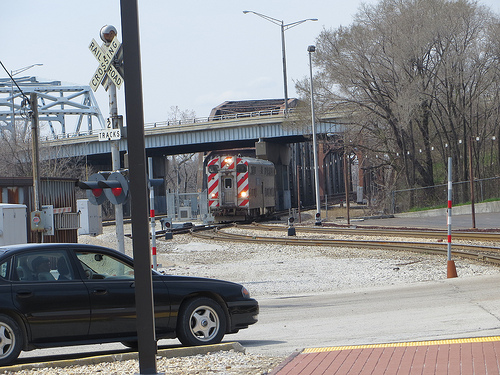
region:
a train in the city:
[18, 21, 486, 333]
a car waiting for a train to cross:
[2, 225, 264, 356]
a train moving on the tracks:
[195, 137, 311, 230]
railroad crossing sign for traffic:
[52, 26, 172, 249]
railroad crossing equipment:
[23, 31, 170, 238]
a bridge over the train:
[28, 93, 390, 227]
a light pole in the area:
[235, 1, 335, 111]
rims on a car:
[181, 293, 233, 348]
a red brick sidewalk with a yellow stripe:
[288, 341, 493, 374]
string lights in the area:
[288, 134, 493, 181]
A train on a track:
[205, 155, 276, 221]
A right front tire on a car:
[177, 297, 226, 344]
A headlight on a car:
[242, 285, 249, 297]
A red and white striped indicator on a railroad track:
[445, 155, 453, 275]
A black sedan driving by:
[0, 243, 257, 368]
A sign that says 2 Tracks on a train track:
[98, 117, 120, 141]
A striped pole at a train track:
[150, 156, 154, 268]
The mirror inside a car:
[93, 253, 103, 260]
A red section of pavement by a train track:
[271, 335, 498, 372]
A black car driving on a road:
[1, 243, 258, 365]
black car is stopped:
[5, 249, 270, 354]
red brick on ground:
[290, 335, 497, 373]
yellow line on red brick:
[304, 323, 495, 365]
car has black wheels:
[172, 290, 232, 337]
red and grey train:
[186, 147, 276, 227]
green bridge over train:
[19, 103, 354, 164]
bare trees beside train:
[304, 20, 495, 183]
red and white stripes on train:
[202, 157, 241, 214]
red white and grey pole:
[426, 152, 473, 274]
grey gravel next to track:
[181, 228, 417, 294]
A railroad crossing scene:
[1, 0, 498, 372]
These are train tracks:
[189, 217, 499, 267]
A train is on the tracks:
[205, 152, 280, 226]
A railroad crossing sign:
[86, 23, 126, 93]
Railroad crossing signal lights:
[74, 170, 131, 207]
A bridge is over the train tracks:
[1, 75, 366, 164]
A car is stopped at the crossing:
[1, 239, 263, 364]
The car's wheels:
[1, 295, 228, 365]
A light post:
[305, 42, 325, 222]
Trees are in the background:
[290, 2, 498, 208]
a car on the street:
[0, 241, 257, 361]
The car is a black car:
[0, 240, 260, 360]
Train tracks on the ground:
[185, 180, 490, 270]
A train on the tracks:
[200, 150, 270, 215]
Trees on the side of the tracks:
[280, 0, 495, 200]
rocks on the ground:
[157, 226, 482, 289]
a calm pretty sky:
[0, 0, 495, 110]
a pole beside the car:
[111, 0, 156, 374]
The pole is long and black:
[118, 0, 156, 373]